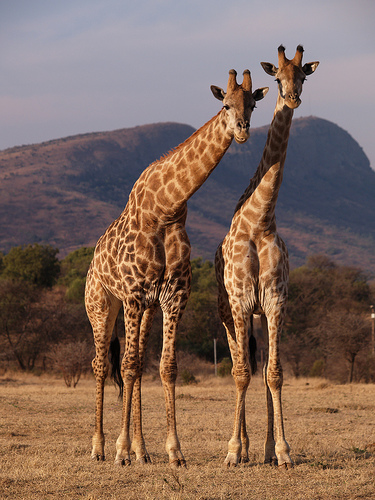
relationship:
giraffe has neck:
[85, 43, 254, 473] [121, 123, 234, 206]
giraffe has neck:
[208, 38, 321, 474] [240, 91, 301, 231]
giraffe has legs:
[85, 43, 254, 473] [78, 286, 200, 470]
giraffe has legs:
[208, 38, 321, 474] [210, 305, 319, 474]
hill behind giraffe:
[10, 114, 370, 260] [85, 43, 254, 473]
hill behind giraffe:
[10, 114, 370, 260] [208, 38, 321, 474]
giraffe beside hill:
[85, 43, 254, 473] [10, 114, 370, 260]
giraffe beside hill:
[208, 38, 321, 474] [10, 114, 370, 260]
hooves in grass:
[78, 442, 303, 467] [6, 371, 370, 488]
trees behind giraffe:
[9, 233, 364, 380] [85, 43, 254, 473]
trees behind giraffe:
[9, 233, 364, 380] [208, 38, 321, 474]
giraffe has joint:
[85, 43, 254, 473] [117, 354, 152, 383]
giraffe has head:
[85, 43, 254, 473] [204, 70, 270, 143]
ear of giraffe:
[207, 83, 226, 105] [85, 43, 254, 473]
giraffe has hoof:
[85, 43, 254, 473] [169, 449, 192, 468]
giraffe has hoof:
[85, 43, 254, 473] [105, 442, 144, 468]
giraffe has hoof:
[208, 38, 321, 474] [276, 456, 300, 474]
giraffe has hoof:
[208, 38, 321, 474] [219, 446, 248, 470]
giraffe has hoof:
[85, 43, 254, 473] [83, 441, 112, 465]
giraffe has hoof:
[85, 43, 254, 473] [133, 451, 154, 468]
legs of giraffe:
[210, 305, 319, 474] [208, 38, 321, 474]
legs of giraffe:
[78, 286, 200, 470] [85, 43, 254, 473]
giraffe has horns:
[85, 43, 254, 473] [229, 69, 256, 90]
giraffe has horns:
[208, 38, 321, 474] [274, 41, 304, 69]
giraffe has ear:
[85, 43, 254, 473] [207, 83, 226, 105]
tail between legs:
[107, 336, 132, 390] [78, 286, 200, 470]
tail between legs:
[246, 331, 265, 374] [210, 305, 319, 474]